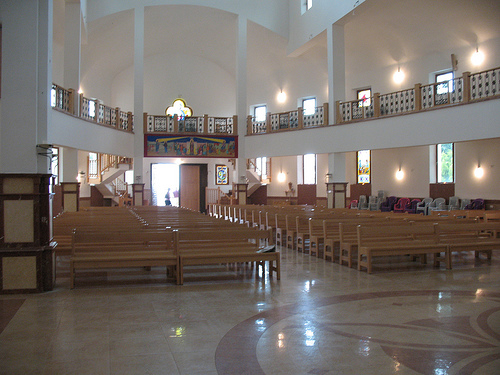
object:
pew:
[50, 204, 499, 289]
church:
[0, 0, 500, 375]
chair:
[381, 196, 485, 218]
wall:
[371, 146, 429, 199]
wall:
[454, 139, 500, 200]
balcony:
[46, 65, 499, 158]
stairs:
[87, 158, 133, 206]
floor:
[0, 241, 500, 375]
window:
[356, 150, 372, 186]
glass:
[358, 150, 370, 186]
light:
[395, 170, 404, 179]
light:
[474, 167, 484, 178]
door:
[180, 164, 199, 211]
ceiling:
[78, 0, 500, 99]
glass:
[437, 143, 454, 184]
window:
[165, 98, 193, 122]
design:
[213, 290, 500, 375]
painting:
[144, 135, 238, 158]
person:
[164, 188, 171, 206]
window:
[300, 0, 312, 15]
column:
[415, 83, 422, 111]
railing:
[379, 88, 416, 116]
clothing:
[256, 244, 276, 253]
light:
[277, 173, 287, 183]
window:
[250, 103, 268, 126]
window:
[297, 96, 316, 116]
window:
[429, 68, 455, 100]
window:
[353, 84, 374, 107]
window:
[90, 98, 104, 117]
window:
[51, 81, 64, 109]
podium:
[144, 98, 238, 136]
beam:
[327, 24, 345, 124]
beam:
[236, 14, 248, 135]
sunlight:
[303, 319, 316, 346]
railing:
[301, 106, 323, 128]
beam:
[133, 8, 144, 131]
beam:
[64, 5, 81, 116]